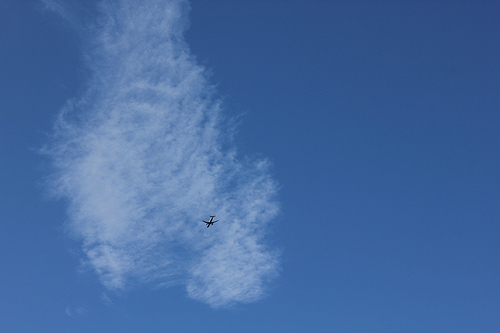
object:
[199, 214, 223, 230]
airplane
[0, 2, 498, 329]
daytime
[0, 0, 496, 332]
sky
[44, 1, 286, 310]
clouds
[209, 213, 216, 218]
tail end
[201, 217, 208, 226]
wing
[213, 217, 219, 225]
wing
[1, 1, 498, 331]
blue sky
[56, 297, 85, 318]
cloud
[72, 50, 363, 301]
sky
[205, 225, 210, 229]
head